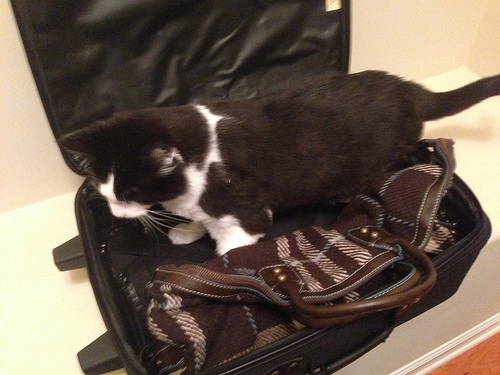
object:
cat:
[58, 71, 500, 260]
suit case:
[8, 0, 490, 375]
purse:
[146, 136, 458, 370]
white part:
[97, 153, 254, 257]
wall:
[1, 2, 500, 213]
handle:
[272, 244, 438, 319]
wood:
[427, 332, 497, 371]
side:
[360, 0, 500, 374]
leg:
[50, 233, 94, 274]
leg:
[76, 327, 128, 374]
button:
[274, 273, 287, 282]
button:
[369, 231, 381, 241]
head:
[60, 107, 193, 222]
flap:
[311, 231, 402, 307]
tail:
[411, 73, 500, 119]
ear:
[138, 137, 181, 181]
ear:
[54, 132, 97, 162]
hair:
[56, 102, 225, 241]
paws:
[164, 215, 206, 247]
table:
[0, 67, 500, 374]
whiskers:
[143, 211, 204, 235]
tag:
[321, 0, 341, 14]